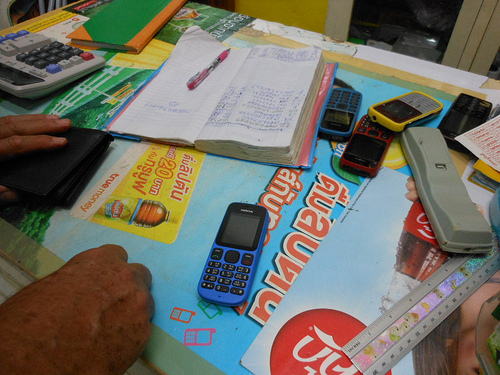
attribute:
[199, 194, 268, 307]
cellphone — blue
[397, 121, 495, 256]
remote — gray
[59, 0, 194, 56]
book — green, orange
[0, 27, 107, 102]
calculator — grey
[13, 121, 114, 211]
wallet — black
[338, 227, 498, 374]
ruler — white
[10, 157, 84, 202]
wallet — black, leather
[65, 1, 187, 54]
notebook — green, orange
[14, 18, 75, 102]
calculator — gray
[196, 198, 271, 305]
phone — blue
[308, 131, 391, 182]
phone — red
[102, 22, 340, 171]
book — open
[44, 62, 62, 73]
button — large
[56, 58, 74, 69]
button — large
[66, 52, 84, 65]
button — large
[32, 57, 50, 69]
button — large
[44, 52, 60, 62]
button — large